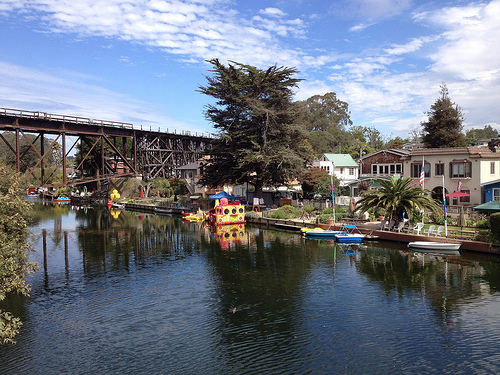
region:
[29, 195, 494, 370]
The water in the canal.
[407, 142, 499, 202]
The beige house on the right.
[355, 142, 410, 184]
The dark brown house on the right.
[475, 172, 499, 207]
The corner of the blue house on the right.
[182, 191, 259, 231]
The yellow and red boat in the water.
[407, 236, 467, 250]
The white boat near the dock.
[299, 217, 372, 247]
The blue boats behind the white boat.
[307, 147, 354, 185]
The white house with the green roof.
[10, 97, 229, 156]
The bridge above the water.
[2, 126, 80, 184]
The trees in the distance.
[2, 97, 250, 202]
train bridge over river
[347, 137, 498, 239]
beach house on river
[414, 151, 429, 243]
American flag behind palm tree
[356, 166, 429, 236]
palm tree by river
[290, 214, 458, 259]
boats in the river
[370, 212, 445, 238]
chairs under the palm tree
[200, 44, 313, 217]
the tree is tall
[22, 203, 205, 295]
bridge reflection in the river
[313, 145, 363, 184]
building roof is green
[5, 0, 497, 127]
scattered clouds in sky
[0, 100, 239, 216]
bridge over the water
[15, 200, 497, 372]
still surface of the water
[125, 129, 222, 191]
wooden substructure of bridge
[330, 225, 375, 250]
blue boat on the shore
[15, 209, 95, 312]
reflection in the water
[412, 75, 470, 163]
evergreen tree behind a building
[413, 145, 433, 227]
flag on a pole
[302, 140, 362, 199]
building with a green roof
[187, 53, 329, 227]
tree close to the water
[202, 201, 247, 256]
yellow object and its reflection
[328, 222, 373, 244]
boat on the water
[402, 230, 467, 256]
boat on the water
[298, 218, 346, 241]
boat on the water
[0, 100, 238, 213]
large metal bridge over water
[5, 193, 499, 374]
body of water with boats in it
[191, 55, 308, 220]
large tree near the water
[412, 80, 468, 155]
large tree near the water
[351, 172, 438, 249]
large tree near the water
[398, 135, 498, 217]
building near the water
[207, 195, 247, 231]
yellow and red childrens toy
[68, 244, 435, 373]
The lake is calm and green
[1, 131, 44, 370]
The tree on the side of the lake is green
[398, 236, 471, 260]
A canoe on the side of the embankment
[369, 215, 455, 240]
The chairs are sitting facing the lake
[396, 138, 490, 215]
The house is off white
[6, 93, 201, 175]
The bridge is iron and brown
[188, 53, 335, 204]
The tree is large and the leaves are green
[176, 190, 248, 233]
A toy lake house is on the lake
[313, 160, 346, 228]
A pole that holds the boat by the dock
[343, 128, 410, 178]
A set of windows on a house